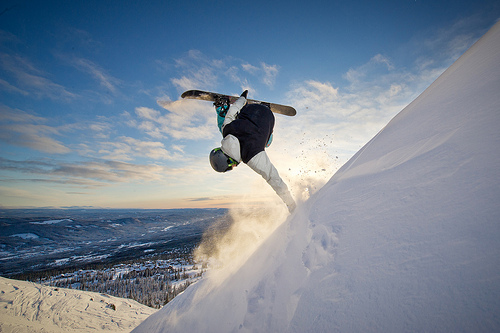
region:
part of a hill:
[383, 177, 397, 189]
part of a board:
[278, 104, 290, 132]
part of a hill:
[134, 276, 143, 285]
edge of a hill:
[330, 232, 337, 239]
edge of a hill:
[446, 208, 453, 220]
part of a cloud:
[150, 171, 152, 208]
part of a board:
[258, 154, 268, 181]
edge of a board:
[241, 144, 283, 186]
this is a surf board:
[182, 85, 308, 115]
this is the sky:
[3, 0, 338, 169]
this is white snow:
[292, 25, 492, 329]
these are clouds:
[41, 158, 151, 198]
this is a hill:
[3, 278, 140, 330]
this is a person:
[207, 93, 298, 221]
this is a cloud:
[18, 105, 66, 155]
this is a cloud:
[343, 60, 400, 106]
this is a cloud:
[162, 97, 191, 145]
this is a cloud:
[259, 55, 279, 90]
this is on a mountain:
[11, 26, 393, 324]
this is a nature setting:
[2, 29, 419, 329]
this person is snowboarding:
[154, 66, 362, 228]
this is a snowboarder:
[132, 51, 311, 193]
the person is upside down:
[154, 75, 334, 212]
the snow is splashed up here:
[190, 195, 307, 275]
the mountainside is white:
[345, 168, 483, 327]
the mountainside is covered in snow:
[345, 179, 465, 313]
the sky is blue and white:
[36, 61, 151, 174]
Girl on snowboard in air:
[168, 60, 311, 201]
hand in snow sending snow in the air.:
[201, 151, 338, 267]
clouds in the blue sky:
[42, 40, 151, 132]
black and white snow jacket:
[218, 99, 280, 159]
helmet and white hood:
[201, 135, 238, 184]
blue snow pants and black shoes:
[212, 95, 228, 125]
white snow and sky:
[352, 97, 467, 294]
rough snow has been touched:
[281, 216, 345, 299]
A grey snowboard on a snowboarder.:
[180, 88, 297, 118]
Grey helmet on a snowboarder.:
[208, 146, 232, 174]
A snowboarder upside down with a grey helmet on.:
[205, 89, 301, 212]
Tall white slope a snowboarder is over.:
[131, 18, 498, 332]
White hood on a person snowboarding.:
[218, 134, 241, 165]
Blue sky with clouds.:
[0, 1, 473, 200]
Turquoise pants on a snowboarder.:
[213, 102, 274, 149]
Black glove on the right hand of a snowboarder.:
[240, 89, 250, 101]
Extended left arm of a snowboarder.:
[248, 154, 295, 214]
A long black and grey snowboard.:
[181, 89, 297, 119]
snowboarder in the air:
[185, 81, 303, 227]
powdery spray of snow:
[185, 140, 324, 262]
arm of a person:
[246, 146, 299, 224]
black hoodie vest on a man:
[217, 104, 278, 157]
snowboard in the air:
[178, 85, 310, 132]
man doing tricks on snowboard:
[152, 52, 305, 204]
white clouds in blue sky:
[106, 131, 144, 163]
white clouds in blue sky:
[54, 149, 91, 181]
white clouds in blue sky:
[71, 40, 112, 67]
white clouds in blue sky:
[330, 67, 367, 116]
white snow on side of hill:
[243, 249, 295, 286]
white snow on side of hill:
[388, 269, 432, 302]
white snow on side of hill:
[437, 129, 480, 185]